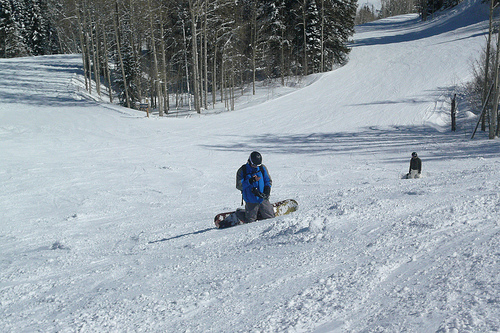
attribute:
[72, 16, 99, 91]
tree — skinny, snow-covered, tall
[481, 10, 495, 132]
tree — tall, skinny, snow-covered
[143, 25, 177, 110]
tree — tall, skinny, snow-covered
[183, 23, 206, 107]
tree — tall, skinny, snow-covered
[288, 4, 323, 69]
tree — tall, skinny, snow-covered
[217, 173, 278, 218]
coat — blue, snow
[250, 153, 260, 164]
helmet — blue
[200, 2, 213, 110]
skinny tree — tall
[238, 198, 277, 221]
pants — grey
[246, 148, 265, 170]
helmet — black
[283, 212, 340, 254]
snow — clumpy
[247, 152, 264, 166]
helmet — black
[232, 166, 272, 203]
jacket — blue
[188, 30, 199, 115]
tree — snow-covered, tall, skinny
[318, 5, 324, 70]
tree — snow-covered, tall, skinny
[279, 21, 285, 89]
tree — snow-covered, tall, skinny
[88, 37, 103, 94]
tree — snow-covered, tall, skinny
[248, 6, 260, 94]
tree — snow-covered, tall, skinny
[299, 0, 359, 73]
tree — green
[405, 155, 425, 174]
coat — black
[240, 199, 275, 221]
sweatpants — grey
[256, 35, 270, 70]
snow — skinny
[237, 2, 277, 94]
tree — tall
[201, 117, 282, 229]
person — wearing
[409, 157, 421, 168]
jacket — black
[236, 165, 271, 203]
coat — blue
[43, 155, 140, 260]
snow — white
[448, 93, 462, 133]
tree stump — small, brown